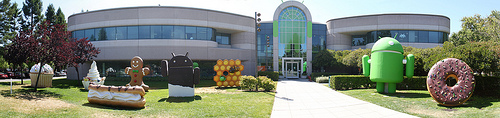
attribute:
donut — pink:
[433, 54, 469, 106]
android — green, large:
[365, 39, 401, 88]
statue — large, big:
[163, 44, 203, 96]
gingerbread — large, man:
[124, 57, 152, 86]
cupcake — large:
[85, 80, 149, 104]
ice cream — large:
[80, 51, 111, 93]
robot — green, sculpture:
[354, 40, 420, 96]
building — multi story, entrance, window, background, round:
[247, 5, 352, 89]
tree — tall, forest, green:
[17, 4, 66, 62]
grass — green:
[217, 93, 265, 114]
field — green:
[222, 92, 246, 101]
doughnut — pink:
[431, 52, 476, 89]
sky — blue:
[82, 7, 89, 9]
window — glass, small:
[155, 22, 193, 38]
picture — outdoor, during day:
[64, 2, 480, 112]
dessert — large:
[25, 30, 228, 111]